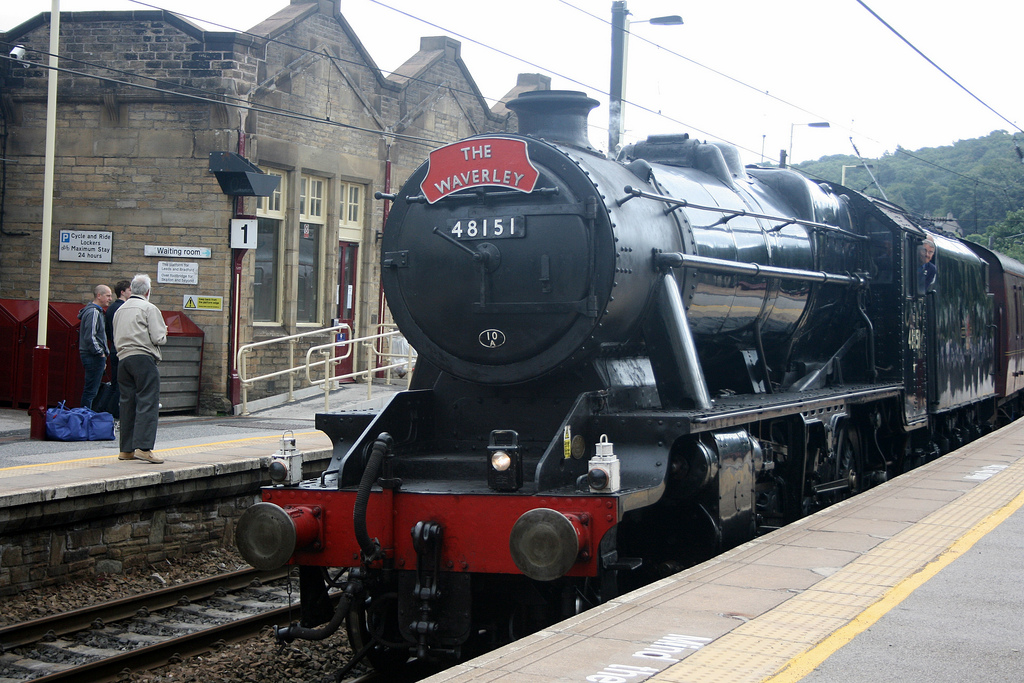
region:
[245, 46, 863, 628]
Train on the tracks.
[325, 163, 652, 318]
Numbers on the train.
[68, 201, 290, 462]
People on the side of the road.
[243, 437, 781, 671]
Red part of the train.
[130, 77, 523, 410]
Windows on the building.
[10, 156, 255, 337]
Signs on the building.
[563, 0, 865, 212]
Lights over the track.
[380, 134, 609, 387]
front of a train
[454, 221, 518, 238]
the numbers are white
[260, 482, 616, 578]
the paint is red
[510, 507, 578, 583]
bumper on the train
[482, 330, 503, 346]
logo on the train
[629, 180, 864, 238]
bar on the side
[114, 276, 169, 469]
a man is standing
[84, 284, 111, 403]
a man is standing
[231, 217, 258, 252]
white and black sign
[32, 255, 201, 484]
Men standing on platform of train station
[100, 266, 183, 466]
Man wearing a white jacket and black pants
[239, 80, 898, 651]
Black engine of passenger train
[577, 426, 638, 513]
white railroad lantern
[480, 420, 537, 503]
Black railroad lantern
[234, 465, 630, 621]
Red front end of train engine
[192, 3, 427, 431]
Front entrance of train station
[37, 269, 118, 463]
Man standing next to blue duffel bag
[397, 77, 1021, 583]
Passenger train at the station platform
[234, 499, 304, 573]
the round metal bumper of the train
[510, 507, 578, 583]
the round metal bumper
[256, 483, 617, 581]
the red portion of the train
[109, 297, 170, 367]
the tan jacket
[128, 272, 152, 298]
the grey hair of the head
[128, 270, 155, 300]
the head of the man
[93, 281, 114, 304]
the head of the man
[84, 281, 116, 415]
the man standing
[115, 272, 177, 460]
the man standing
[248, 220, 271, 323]
glass window pane on building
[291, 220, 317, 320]
glass window pane on building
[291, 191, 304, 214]
glass window pane on building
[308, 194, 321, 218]
glass window pane on building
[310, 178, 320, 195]
glass window pane on building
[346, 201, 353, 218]
glass window pane on building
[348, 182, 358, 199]
glass window pane on building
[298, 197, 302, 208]
glass window pane on building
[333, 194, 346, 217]
glass window pane on building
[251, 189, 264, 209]
glass window pane on building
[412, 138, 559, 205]
red sign on front of train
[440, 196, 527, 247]
white numbers on front of train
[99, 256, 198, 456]
man wearing tan jacket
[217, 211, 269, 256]
white sign with one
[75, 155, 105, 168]
A brick in a building.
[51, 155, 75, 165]
A brick in a building.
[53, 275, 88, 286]
A brick in a building.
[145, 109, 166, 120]
A brick in a building.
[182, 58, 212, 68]
A brick in a building.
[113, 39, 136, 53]
A brick in a building.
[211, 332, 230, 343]
A brick in a building.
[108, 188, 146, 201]
A brick in a building.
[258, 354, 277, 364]
A brick in a building.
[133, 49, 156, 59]
A brick in a building.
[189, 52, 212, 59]
A brick in a building.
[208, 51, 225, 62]
A brick in a building.